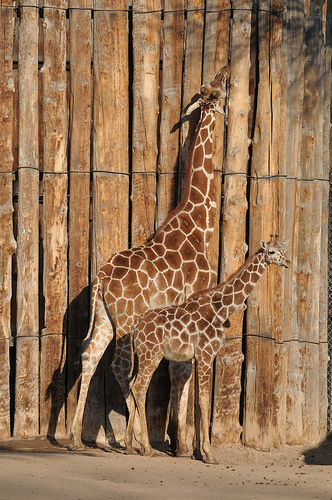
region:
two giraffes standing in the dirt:
[34, 59, 302, 462]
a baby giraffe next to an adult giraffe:
[63, 55, 296, 465]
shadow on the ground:
[300, 435, 331, 466]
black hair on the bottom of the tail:
[121, 372, 135, 381]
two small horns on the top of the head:
[266, 231, 278, 244]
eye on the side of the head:
[266, 250, 275, 257]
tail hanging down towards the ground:
[73, 277, 107, 350]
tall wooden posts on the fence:
[0, 1, 330, 449]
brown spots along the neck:
[216, 254, 269, 311]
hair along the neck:
[181, 250, 262, 298]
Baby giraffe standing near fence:
[124, 233, 290, 463]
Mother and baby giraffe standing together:
[69, 65, 292, 463]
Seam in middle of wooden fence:
[0, 165, 331, 183]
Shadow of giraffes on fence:
[44, 284, 169, 454]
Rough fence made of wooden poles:
[2, 0, 330, 450]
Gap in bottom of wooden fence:
[237, 301, 246, 445]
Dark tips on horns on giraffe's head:
[269, 232, 278, 237]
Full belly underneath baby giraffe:
[163, 330, 193, 361]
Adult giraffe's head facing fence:
[183, 64, 231, 119]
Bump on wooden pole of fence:
[8, 238, 16, 254]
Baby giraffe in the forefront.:
[117, 230, 294, 465]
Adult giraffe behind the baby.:
[60, 63, 230, 456]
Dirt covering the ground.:
[0, 431, 329, 495]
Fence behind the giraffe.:
[0, 1, 328, 445]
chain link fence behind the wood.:
[319, 91, 327, 433]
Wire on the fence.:
[0, 2, 327, 19]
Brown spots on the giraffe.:
[119, 230, 294, 460]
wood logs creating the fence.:
[0, 0, 327, 453]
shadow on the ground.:
[295, 425, 330, 471]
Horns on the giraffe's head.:
[260, 229, 291, 269]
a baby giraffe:
[119, 238, 295, 465]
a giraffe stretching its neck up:
[92, 62, 235, 311]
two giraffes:
[74, 63, 290, 463]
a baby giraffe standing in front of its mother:
[58, 61, 290, 467]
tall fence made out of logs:
[2, 5, 68, 437]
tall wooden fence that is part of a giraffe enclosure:
[1, 1, 325, 445]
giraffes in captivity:
[57, 61, 292, 464]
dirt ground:
[1, 438, 330, 497]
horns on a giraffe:
[195, 82, 223, 102]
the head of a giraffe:
[255, 231, 294, 273]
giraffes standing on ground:
[69, 51, 306, 476]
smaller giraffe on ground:
[122, 233, 285, 457]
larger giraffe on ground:
[71, 59, 260, 426]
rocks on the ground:
[118, 453, 311, 498]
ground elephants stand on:
[18, 459, 301, 499]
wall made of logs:
[7, 8, 309, 425]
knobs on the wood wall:
[223, 348, 248, 366]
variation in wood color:
[261, 369, 319, 413]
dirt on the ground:
[3, 434, 48, 452]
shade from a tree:
[266, 16, 331, 115]